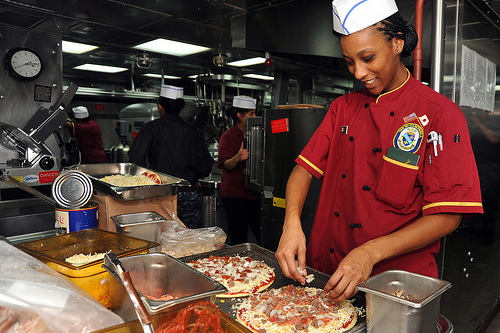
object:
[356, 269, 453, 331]
container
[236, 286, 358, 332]
pizza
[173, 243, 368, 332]
tray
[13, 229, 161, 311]
container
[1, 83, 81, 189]
deli slicer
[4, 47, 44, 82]
clock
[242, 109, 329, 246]
oven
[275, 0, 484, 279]
woman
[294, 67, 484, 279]
shirt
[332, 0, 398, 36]
hat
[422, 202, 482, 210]
trim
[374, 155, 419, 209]
pocket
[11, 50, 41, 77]
clock face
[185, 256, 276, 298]
pizza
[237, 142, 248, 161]
hand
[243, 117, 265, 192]
oven door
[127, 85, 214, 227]
person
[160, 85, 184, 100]
hat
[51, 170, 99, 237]
can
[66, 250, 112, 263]
cheese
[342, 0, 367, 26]
stripe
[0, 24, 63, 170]
wall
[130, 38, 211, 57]
light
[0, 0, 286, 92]
ceiling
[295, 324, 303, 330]
sausage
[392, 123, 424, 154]
patch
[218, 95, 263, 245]
person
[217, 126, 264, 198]
uniform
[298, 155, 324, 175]
trim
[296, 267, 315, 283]
cheese